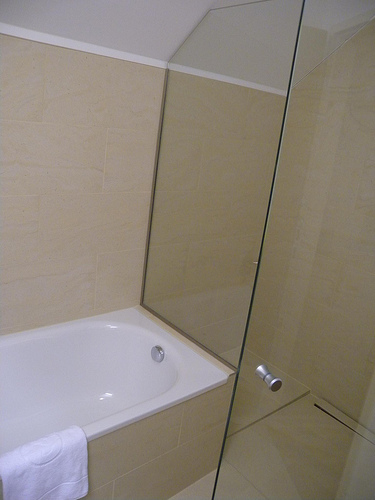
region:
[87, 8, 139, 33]
The ceiling is white.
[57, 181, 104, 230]
The wall is off white.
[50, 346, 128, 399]
The tub is white.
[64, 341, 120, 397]
The tub is clean.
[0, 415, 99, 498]
A towel is on the tub.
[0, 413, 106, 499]
The towel is white.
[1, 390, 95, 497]
The towel is clean.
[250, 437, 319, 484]
The floor is off white.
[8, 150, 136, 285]
The wall is tile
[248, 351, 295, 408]
The knob is gray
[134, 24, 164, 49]
part of a cei;ling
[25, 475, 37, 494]
part of a towel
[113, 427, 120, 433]
edge of a tab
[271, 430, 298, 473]
part of a glass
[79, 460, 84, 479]
edge of a towel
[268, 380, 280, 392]
edge of a handle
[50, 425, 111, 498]
white towel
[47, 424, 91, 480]
white towel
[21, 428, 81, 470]
the towel is white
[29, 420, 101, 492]
the towel is white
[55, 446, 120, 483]
the towel is white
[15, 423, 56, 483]
the towel is white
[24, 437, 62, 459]
the towel is white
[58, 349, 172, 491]
a tub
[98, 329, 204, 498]
a tub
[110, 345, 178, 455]
a tub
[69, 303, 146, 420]
a tub